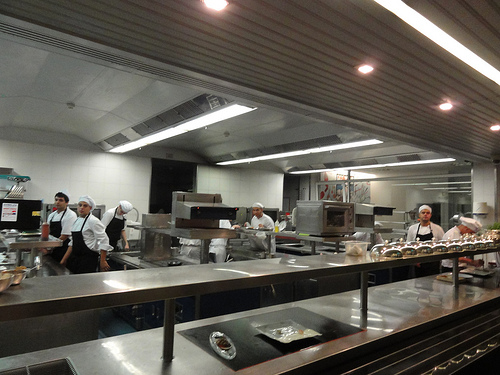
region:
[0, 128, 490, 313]
The people are in a kitchen.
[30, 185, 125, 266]
Two people standing next to each other.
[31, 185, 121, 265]
The people are wearing black aprons.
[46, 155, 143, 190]
The wall is white.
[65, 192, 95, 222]
The person is wearing a hat.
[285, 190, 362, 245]
An oven in the kitchen.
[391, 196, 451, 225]
This man is wearing a hat.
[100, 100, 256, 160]
A light on the ceiling.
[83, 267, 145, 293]
A reflection of the light.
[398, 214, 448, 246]
Person wearing a black apron.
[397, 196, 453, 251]
man in white clothes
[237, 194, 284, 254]
man in white clothes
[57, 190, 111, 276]
man in white clothes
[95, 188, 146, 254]
man in white clothes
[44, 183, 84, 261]
man in white clothes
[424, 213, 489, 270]
man in white clothes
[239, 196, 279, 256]
man in white hat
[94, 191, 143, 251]
man in white hat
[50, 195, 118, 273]
man in white hat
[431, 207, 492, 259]
man in white hat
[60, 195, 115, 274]
worker in an apron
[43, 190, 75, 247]
worker wearing an apron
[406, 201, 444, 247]
worker wearing an apron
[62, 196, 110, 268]
a hair net on a worker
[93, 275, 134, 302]
reflection of light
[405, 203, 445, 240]
a hair net on a worker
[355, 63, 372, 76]
light above the cafeteria line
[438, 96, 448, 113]
light above cafeteria line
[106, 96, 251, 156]
a row of florescent lights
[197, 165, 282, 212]
white wall in distance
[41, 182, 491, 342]
too many cooks in the kitchen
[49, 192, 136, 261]
men wearing aprons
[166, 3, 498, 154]
the lights on top of the cieling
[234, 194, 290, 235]
the man who is by him self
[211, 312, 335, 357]
food that looks ready to go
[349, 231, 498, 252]
food on top of the shelf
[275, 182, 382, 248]
a big oven to cook in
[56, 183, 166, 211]
three guys wearing chef hats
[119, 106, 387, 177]
lights in the kitchen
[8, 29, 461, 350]
the industrial kitchen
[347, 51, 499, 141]
illuminated lights in a kitchen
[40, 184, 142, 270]
cooks in a kitchen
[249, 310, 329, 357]
empty plate of food on counter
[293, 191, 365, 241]
microwave oven in a kitchen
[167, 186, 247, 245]
warmer for food in a kitchen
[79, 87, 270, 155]
lights on ceiling of a kitchen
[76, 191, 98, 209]
hat on cook's head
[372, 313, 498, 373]
shelf for a cafeteria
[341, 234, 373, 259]
plastic container on counter top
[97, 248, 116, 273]
left arm of a cook